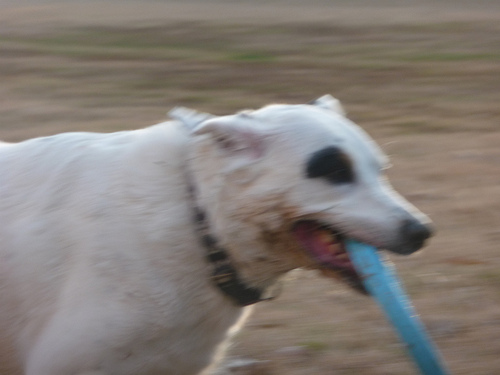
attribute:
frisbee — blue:
[362, 247, 442, 287]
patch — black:
[263, 145, 385, 223]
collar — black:
[170, 169, 230, 280]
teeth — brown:
[246, 194, 380, 314]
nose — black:
[403, 213, 423, 242]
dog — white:
[13, 234, 193, 321]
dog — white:
[54, 245, 252, 354]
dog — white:
[21, 173, 314, 334]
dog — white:
[54, 238, 252, 372]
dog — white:
[106, 134, 303, 323]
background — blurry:
[108, 17, 486, 232]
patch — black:
[305, 141, 359, 187]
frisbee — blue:
[346, 232, 436, 364]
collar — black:
[168, 142, 248, 291]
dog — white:
[18, 33, 469, 373]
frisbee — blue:
[360, 240, 458, 367]